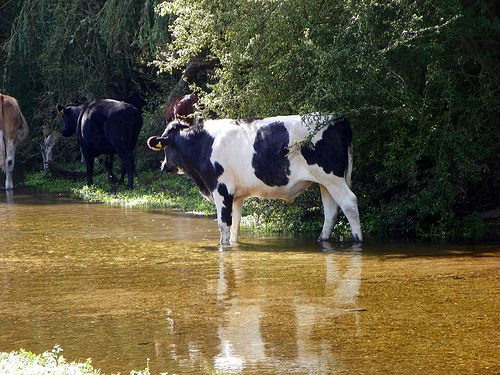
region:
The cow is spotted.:
[147, 109, 374, 251]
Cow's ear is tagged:
[147, 137, 163, 149]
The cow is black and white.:
[145, 112, 372, 252]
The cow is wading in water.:
[146, 110, 376, 261]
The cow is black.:
[51, 95, 143, 195]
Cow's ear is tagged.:
[54, 102, 64, 115]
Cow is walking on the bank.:
[53, 94, 149, 201]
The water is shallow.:
[2, 183, 497, 373]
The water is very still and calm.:
[0, 177, 498, 373]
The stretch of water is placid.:
[0, 186, 497, 371]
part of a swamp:
[288, 274, 343, 321]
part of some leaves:
[409, 159, 457, 206]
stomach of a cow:
[246, 150, 291, 191]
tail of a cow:
[342, 164, 352, 186]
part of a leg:
[219, 204, 236, 224]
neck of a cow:
[178, 142, 201, 187]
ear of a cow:
[141, 124, 173, 161]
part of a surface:
[147, 280, 208, 326]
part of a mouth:
[156, 151, 178, 179]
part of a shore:
[113, 180, 158, 216]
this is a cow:
[145, 109, 370, 270]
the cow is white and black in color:
[159, 110, 364, 259]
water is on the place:
[81, 266, 496, 368]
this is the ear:
[146, 131, 166, 150]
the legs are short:
[318, 180, 357, 246]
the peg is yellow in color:
[154, 142, 161, 149]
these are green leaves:
[276, 10, 457, 96]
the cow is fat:
[59, 92, 135, 197]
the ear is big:
[146, 134, 166, 149]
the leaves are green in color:
[233, 10, 400, 93]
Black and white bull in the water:
[143, 86, 377, 263]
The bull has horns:
[137, 116, 194, 159]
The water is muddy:
[67, 257, 292, 332]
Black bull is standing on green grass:
[43, 95, 154, 183]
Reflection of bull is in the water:
[145, 246, 418, 371]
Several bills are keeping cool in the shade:
[3, 60, 184, 200]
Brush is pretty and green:
[142, 4, 499, 94]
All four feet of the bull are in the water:
[192, 190, 402, 261]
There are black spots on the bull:
[233, 121, 340, 191]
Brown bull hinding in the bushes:
[153, 87, 210, 119]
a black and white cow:
[98, 77, 456, 278]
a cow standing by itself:
[121, 55, 496, 322]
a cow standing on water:
[82, 173, 421, 373]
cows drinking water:
[30, 62, 265, 248]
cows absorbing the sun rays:
[0, 61, 458, 330]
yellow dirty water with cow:
[32, 84, 424, 351]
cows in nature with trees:
[123, 0, 464, 287]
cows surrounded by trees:
[83, 0, 402, 266]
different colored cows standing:
[7, 37, 408, 321]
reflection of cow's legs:
[268, 216, 406, 328]